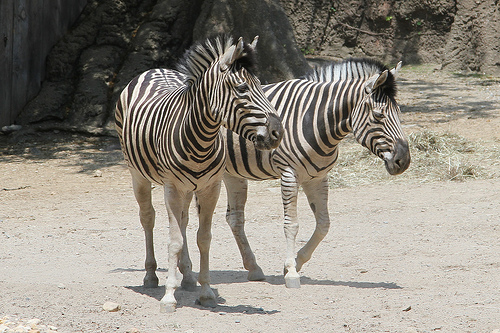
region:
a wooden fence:
[0, 0, 76, 127]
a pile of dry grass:
[325, 121, 492, 187]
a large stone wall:
[280, 0, 496, 76]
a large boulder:
[16, 3, 308, 133]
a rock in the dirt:
[102, 300, 120, 310]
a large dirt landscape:
[0, 67, 495, 329]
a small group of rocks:
[0, 307, 60, 329]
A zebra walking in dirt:
[108, 25, 283, 310]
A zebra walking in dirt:
[215, 55, 408, 292]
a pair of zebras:
[113, 33, 413, 314]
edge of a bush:
[423, 140, 434, 166]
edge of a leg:
[282, 256, 291, 260]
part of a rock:
[465, 64, 475, 77]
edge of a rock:
[78, 84, 91, 116]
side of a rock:
[94, 105, 111, 122]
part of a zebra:
[286, 221, 314, 248]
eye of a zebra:
[375, 108, 387, 125]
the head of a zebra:
[201, 1, 365, 158]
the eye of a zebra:
[225, 79, 253, 110]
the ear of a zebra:
[224, 1, 288, 69]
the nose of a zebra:
[230, 115, 291, 152]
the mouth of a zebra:
[237, 92, 351, 159]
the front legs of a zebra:
[154, 201, 239, 303]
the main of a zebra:
[154, 25, 278, 140]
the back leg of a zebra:
[131, 132, 191, 290]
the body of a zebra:
[107, 52, 249, 192]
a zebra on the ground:
[92, 32, 382, 313]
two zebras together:
[53, 32, 415, 316]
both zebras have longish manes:
[176, 25, 396, 93]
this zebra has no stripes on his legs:
[111, 162, 241, 316]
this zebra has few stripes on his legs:
[235, 173, 341, 298]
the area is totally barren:
[3, 43, 488, 326]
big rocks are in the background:
[43, 4, 294, 38]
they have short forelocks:
[231, 44, 411, 97]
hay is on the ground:
[415, 133, 495, 173]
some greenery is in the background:
[368, 5, 433, 36]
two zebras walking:
[111, 33, 409, 315]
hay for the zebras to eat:
[302, 116, 488, 186]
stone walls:
[15, 2, 496, 124]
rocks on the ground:
[10, 298, 125, 325]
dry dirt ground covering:
[10, 128, 486, 324]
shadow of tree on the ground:
[316, 48, 487, 134]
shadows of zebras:
[111, 252, 417, 312]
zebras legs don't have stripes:
[116, 170, 226, 306]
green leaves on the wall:
[376, 10, 392, 25]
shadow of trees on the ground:
[2, 124, 153, 175]